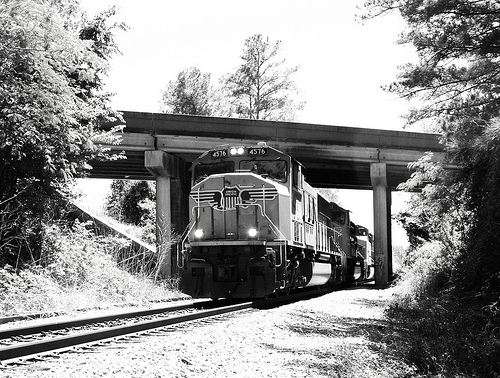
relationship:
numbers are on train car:
[249, 147, 266, 154] [164, 133, 381, 296]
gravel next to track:
[155, 342, 199, 361] [6, 297, 273, 363]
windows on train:
[194, 156, 290, 186] [176, 141, 375, 301]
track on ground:
[0, 293, 340, 370] [1, 276, 497, 376]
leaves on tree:
[391, 259, 453, 326] [361, 8, 498, 366]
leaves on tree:
[391, 130, 476, 250] [390, 145, 463, 255]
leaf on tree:
[407, 161, 411, 165] [1, 0, 128, 270]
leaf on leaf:
[407, 161, 411, 165] [411, 162, 414, 166]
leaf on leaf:
[407, 161, 411, 165] [419, 156, 424, 160]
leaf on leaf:
[407, 161, 411, 165] [421, 185, 426, 190]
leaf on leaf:
[407, 161, 411, 165] [430, 191, 437, 196]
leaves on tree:
[227, 35, 258, 95] [221, 40, 299, 122]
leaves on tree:
[187, 90, 197, 105] [164, 61, 216, 118]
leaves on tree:
[0, 0, 130, 191] [1, 0, 128, 270]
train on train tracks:
[160, 130, 357, 334] [69, 275, 222, 342]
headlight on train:
[247, 225, 258, 237] [176, 141, 375, 301]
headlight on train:
[192, 227, 204, 239] [176, 141, 375, 301]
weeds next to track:
[7, 229, 171, 312] [4, 295, 264, 339]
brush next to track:
[34, 224, 176, 307] [4, 295, 264, 339]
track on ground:
[0, 285, 340, 370] [1, 205, 419, 377]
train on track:
[176, 141, 375, 301] [1, 295, 253, 368]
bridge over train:
[72, 101, 467, 293] [176, 141, 375, 301]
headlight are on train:
[192, 227, 204, 239] [180, 129, 391, 298]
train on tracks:
[176, 141, 375, 301] [0, 287, 346, 370]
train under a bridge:
[176, 141, 375, 301] [175, 134, 373, 300]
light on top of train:
[237, 145, 245, 157] [176, 141, 375, 301]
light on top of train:
[227, 147, 237, 154] [176, 141, 375, 301]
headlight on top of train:
[247, 225, 258, 237] [176, 141, 375, 301]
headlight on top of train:
[192, 227, 204, 239] [176, 141, 375, 301]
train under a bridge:
[176, 141, 375, 301] [68, 98, 472, 193]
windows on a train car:
[194, 156, 286, 186] [152, 139, 381, 307]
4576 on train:
[202, 145, 249, 174] [155, 110, 382, 273]